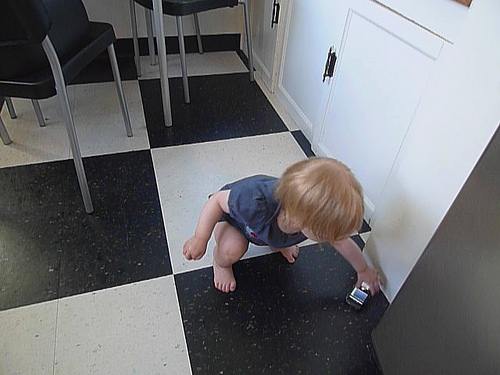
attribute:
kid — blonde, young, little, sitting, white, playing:
[211, 135, 361, 292]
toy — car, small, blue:
[342, 273, 374, 315]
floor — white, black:
[108, 157, 177, 301]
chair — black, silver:
[15, 16, 148, 198]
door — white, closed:
[276, 19, 440, 127]